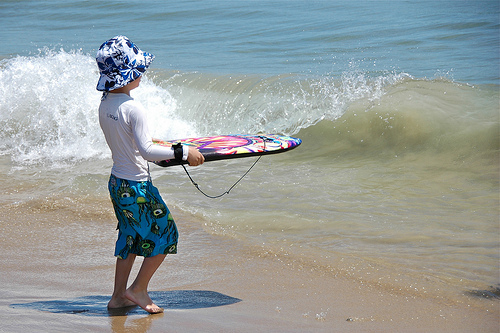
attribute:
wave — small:
[267, 35, 443, 187]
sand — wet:
[25, 206, 480, 331]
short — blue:
[101, 175, 238, 284]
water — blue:
[209, 21, 461, 101]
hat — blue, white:
[90, 36, 159, 90]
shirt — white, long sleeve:
[91, 89, 172, 187]